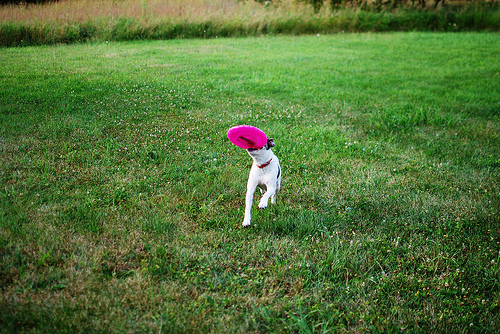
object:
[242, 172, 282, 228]
feet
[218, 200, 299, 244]
ground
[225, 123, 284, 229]
playing frisbee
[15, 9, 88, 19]
weeds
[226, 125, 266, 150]
frisbee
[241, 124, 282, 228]
dog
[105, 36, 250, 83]
field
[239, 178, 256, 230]
leg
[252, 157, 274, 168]
collar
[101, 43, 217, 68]
spots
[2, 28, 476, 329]
lawn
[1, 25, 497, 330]
grass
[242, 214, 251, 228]
paw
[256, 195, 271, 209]
paw